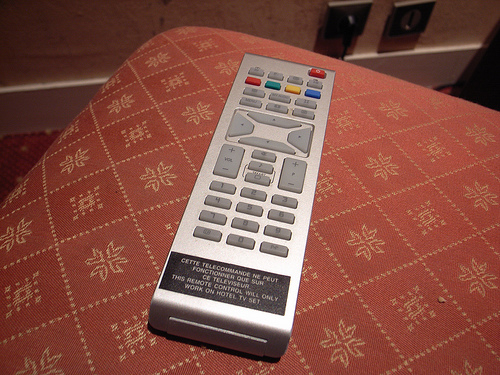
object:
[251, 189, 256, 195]
number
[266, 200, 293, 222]
black number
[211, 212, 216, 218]
number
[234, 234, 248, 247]
black number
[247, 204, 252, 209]
number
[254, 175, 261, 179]
number